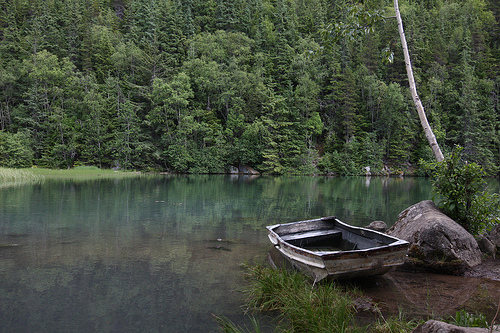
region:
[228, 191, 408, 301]
Empty boat on the riverside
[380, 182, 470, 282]
Large boulder on riverside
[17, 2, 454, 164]
Large forest with mature trees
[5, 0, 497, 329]
Wide river and forest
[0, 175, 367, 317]
Reflective surface on river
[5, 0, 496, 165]
Green mature trees in the background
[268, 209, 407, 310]
Boat is made of wood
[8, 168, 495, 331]
River has soot througout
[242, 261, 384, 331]
Tall grass along riverside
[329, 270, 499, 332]
Dirt along tall grass and riverside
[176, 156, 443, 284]
"Abandoned boat in shallow water"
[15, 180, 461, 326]
"Lonely, shallow waters"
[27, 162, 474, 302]
"Little boat in shallow water"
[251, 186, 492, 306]
"Big rock, little boat"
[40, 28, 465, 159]
"Green, wooded area"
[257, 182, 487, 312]
"Boat near a rock"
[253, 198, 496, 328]
"A boat parked on shore"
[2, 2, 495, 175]
"Lots and lots of trees"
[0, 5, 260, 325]
"Trees and water side by side"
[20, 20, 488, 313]
"A quiet and peaceful place"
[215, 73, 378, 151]
Trees in the woods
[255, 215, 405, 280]
Empty boat on a lake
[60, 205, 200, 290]
a lake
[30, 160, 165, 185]
Tall grass by a lake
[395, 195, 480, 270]
A boulder on the shore of a lake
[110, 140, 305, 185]
The shore with trees by a lake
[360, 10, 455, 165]
A tall tree overhanging a lake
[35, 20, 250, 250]
A lake by the woods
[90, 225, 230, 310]
A shallow lake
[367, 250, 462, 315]
Muddy water near a lake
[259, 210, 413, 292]
There is an old boat shown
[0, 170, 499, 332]
The water is reflective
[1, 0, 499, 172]
Trees cover the background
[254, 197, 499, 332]
The boat is next to a big rock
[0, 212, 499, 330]
The boat is on the sandbar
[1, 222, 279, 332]
The water is shallow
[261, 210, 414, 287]
The boat is damaged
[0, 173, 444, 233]
Water is reflecting trees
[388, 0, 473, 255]
single tree is by the rock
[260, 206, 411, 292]
Boat is made of metal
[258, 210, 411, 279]
boat sitting in the water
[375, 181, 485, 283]
large river rock in the water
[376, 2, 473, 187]
bare tree trunk leaning over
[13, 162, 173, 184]
green grass beside water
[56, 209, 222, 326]
dirty colored water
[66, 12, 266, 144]
several kinds of green trees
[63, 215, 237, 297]
very shallow water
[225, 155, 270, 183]
large rock between trees and water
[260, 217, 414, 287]
old wooden boat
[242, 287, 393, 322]
grass growing out of shallow water